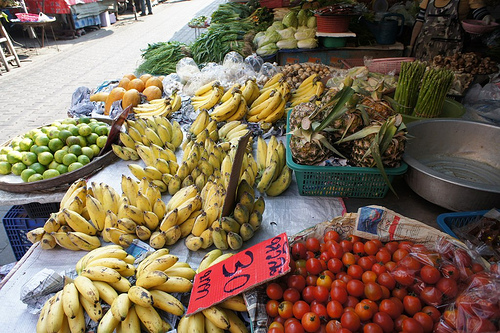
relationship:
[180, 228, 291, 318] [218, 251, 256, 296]
sign has price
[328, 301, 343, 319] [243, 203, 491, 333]
tomatoes on top of newspaper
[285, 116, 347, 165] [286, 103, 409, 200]
pineapples in display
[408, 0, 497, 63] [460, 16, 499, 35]
woman carrying bowl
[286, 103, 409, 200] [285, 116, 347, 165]
display of pineapples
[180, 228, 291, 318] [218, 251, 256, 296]
sign reads price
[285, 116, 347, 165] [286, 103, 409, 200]
pineapples on display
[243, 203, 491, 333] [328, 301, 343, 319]
newspaper of tomatoes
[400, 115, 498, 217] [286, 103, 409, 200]
pan behind display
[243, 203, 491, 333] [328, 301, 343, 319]
newspaper underneath tomatoes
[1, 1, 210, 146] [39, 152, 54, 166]
street in front of limes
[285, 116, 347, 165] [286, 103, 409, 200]
pineapples are in display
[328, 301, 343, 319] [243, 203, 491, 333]
tomatoes piled on newspaper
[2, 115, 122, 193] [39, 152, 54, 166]
tray full of limes